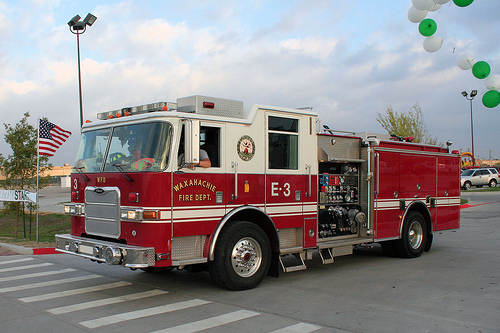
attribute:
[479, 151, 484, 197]
suv — silver